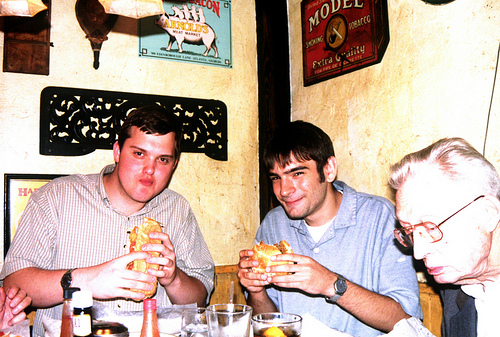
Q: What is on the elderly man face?
A: Glasses.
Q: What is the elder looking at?
A: Downward.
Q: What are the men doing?
A: Eating food.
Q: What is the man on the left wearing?
A: Checkered shirt.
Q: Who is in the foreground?
A: 2 men.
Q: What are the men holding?
A: Sandwiches.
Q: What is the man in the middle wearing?
A: Blue shirt.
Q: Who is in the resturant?
A: 3 men.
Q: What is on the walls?
A: Wall art.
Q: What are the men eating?
A: Sandwiches.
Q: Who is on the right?
A: An old man.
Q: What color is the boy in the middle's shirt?
A: Blue.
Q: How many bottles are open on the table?
A: 1.